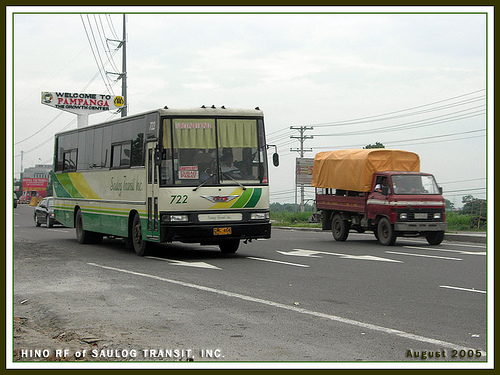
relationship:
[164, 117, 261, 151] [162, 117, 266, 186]
shade at top of windshield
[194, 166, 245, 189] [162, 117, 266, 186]
wipers are in front of windshield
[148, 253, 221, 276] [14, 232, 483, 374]
arrow sign on top of road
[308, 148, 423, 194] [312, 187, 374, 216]
canopy covering truck bed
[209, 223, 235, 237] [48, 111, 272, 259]
license plate in front of bus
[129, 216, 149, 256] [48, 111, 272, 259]
tires are underneath bus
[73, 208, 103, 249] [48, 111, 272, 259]
tires are underneath bus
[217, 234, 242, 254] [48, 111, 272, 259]
tires are underneath bus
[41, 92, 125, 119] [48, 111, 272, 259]
pampanga sign above bus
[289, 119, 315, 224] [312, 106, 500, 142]
pole holds up power lines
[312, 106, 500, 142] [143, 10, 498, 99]
power lines are hanging in air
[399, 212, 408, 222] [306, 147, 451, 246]
headlights are in front of truck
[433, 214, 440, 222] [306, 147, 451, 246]
headlights are in front of truck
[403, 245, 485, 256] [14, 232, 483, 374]
arrow sign are on top of road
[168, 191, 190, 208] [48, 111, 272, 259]
number 722 on front of a bus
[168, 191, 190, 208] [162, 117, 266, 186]
number 722 underneath windshield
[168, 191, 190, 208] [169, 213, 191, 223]
number 722 above headlights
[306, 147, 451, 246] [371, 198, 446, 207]
truck has a stripe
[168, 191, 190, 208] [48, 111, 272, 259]
number 722 in front of bus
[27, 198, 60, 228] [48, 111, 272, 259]
car behind bus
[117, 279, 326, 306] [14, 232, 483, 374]
lines are on top of road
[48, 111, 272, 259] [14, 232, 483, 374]
bus traveling on road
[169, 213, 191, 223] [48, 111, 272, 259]
headlights are in front of bus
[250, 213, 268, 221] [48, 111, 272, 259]
headlights are in front of bus